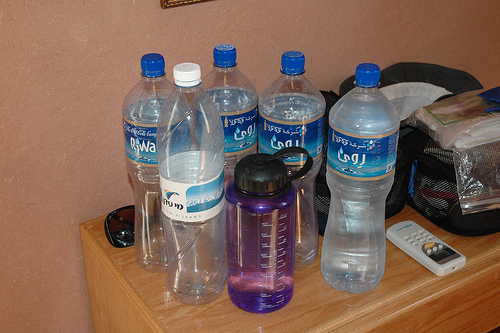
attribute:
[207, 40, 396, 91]
bottle caps — blue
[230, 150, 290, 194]
lid — black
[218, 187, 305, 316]
tumbler — purple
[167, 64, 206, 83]
cap — white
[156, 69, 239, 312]
water bottle — empty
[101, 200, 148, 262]
sunglasses — brown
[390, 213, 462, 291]
remote control — white